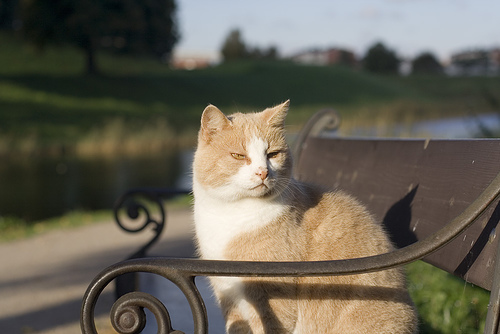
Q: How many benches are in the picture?
A: One.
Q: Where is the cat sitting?
A: A bench.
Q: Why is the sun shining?
A: It's daytime.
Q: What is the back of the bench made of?
A: Wood.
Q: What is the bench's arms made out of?
A: Metal.